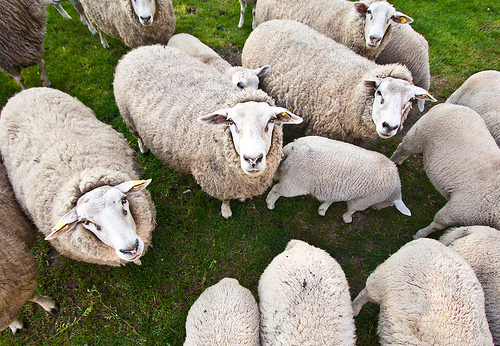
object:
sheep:
[111, 42, 309, 218]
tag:
[219, 111, 232, 120]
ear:
[193, 107, 229, 129]